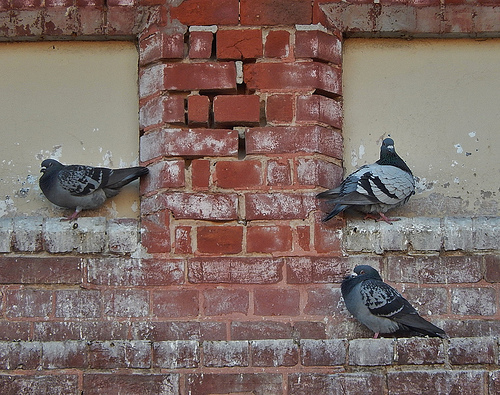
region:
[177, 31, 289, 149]
Red repair bricks in wall.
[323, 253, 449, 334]
Gray pigeon on ledge.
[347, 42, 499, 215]
Tan wall on building.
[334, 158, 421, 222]
Light gray feathers on bird.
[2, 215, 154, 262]
Brick ledge on the building.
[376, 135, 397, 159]
White on bird's beak.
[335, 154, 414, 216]
Black tips on the bird's feathers.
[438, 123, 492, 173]
Chips in the paint on the wall.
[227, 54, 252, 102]
Hole in the bricks.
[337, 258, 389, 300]
Black colored head on bird.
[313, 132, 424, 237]
a bird standing near a brick fireplace.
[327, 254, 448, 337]
a pigeon on a brick structure.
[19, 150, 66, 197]
the head of a bird.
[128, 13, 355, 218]
a brick chimney on a home.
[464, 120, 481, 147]
chipped paint on a wall.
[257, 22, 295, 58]
a brick on a chimney.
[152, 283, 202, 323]
a brick near a bird.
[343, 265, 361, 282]
a beak on a bird.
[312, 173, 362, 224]
tail feathers on a bird.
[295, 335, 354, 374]
a brick on a brick wall.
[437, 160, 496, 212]
A grey scarred wall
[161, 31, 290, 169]
Red colored gapped tiles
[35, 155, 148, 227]
A beautiful grey dove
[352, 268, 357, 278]
A small white beak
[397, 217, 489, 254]
Sand tainted red bricks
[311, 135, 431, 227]
White and grey duck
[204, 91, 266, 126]
A red stone brick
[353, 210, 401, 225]
Short wide spread feet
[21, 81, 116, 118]
A grey colored wall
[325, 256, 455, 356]
A beautiful innocent duck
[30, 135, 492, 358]
three pigeons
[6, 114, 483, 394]
the pigeons are fat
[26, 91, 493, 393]
the three pigeons are large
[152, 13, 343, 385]
red brick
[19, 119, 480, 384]
the pigeons are on a ledge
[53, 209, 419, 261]
the pigeon have red feet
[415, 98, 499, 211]
the wall's paint is chipped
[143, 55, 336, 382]
there is white debris on the bricks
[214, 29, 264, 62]
this brick is cracked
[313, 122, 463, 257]
this pigeon has lighter feathers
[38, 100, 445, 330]
three gray and black birds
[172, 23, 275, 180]
loose bricks of building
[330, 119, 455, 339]
two birds on same side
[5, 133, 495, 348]
three birds perched on ledges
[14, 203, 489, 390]
white discoloration on bricks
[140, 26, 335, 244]
brick column dividing ledges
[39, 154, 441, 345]
two birds looking to their right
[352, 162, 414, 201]
light grey wing of bird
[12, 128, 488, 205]
white paint on beige background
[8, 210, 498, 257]
two white ledges